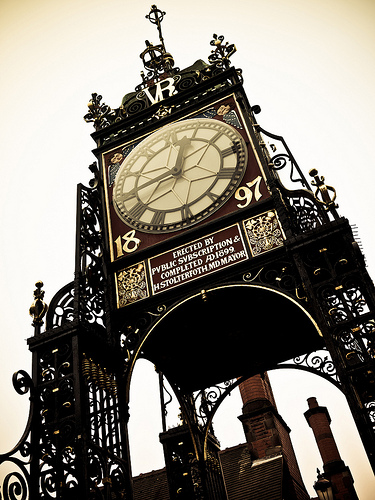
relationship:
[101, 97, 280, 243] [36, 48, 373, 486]
clock on tower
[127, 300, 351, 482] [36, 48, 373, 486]
peak on tower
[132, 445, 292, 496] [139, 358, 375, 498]
roof on church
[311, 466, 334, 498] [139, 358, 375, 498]
lamp beside church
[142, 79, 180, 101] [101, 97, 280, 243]
initials are on clock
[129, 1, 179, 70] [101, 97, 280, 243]
spheres on clock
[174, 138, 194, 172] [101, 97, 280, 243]
hand on clock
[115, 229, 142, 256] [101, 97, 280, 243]
18 on clock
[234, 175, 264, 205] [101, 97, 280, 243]
97 on clock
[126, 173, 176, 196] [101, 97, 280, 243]
hand on clock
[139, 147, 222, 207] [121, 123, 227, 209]
star on face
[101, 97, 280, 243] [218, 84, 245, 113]
clock has corner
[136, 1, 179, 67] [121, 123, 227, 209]
parapets are above face